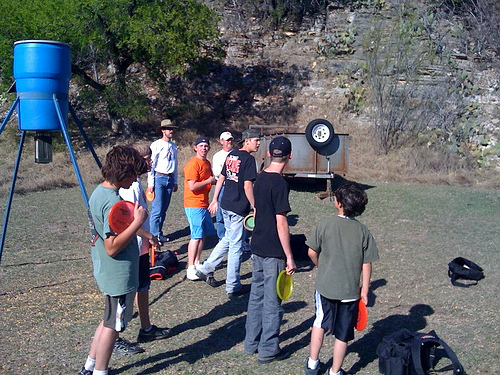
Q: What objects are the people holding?
A: Frisbees.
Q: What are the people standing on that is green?
A: Grass.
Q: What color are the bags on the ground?
A: Black.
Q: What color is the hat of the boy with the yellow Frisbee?
A: Black.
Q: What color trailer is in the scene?
A: Grey.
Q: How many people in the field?
A: Eight.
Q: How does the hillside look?
A: Rocky.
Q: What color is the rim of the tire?
A: White.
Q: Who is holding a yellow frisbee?
A: The boy in the black shirt with a hat.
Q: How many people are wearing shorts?
A: 4.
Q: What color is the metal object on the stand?
A: Blue.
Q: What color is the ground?
A: Grey.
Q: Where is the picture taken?
A: Near a rock face.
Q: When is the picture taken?
A: Daytime.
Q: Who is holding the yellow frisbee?
A: The boy.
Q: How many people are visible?
A: Eight.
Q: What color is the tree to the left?
A: Green.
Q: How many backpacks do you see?
A: Three.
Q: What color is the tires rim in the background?
A: White.